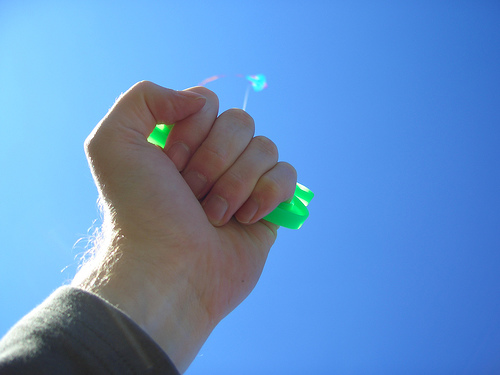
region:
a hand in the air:
[30, 59, 395, 269]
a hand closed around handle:
[64, 53, 371, 273]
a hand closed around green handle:
[49, 44, 381, 296]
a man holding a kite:
[42, 73, 401, 359]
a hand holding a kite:
[47, 6, 403, 310]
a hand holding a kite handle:
[22, 35, 384, 287]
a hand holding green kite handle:
[57, 32, 410, 296]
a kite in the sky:
[209, 31, 342, 165]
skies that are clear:
[321, 68, 494, 339]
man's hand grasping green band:
[82, 80, 296, 321]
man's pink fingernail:
[201, 193, 228, 225]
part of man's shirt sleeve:
[0, 285, 181, 373]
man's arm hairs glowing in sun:
[59, 192, 126, 296]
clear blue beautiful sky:
[2, 0, 497, 372]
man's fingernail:
[165, 141, 190, 172]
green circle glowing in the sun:
[250, 75, 265, 91]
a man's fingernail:
[182, 170, 205, 198]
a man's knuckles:
[135, 78, 296, 180]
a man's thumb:
[84, 80, 206, 232]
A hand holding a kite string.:
[70, 40, 335, 320]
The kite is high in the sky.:
[231, 60, 277, 95]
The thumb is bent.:
[80, 75, 195, 205]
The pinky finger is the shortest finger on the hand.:
[240, 155, 300, 230]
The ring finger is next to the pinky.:
[200, 130, 275, 230]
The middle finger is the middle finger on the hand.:
[180, 105, 240, 195]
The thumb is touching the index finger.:
[155, 80, 220, 165]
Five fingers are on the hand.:
[80, 35, 315, 280]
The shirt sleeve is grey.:
[0, 280, 196, 374]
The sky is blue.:
[360, 5, 498, 336]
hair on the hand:
[52, 227, 123, 287]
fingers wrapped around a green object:
[107, 75, 303, 241]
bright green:
[112, 110, 344, 235]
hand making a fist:
[66, 60, 341, 315]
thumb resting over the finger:
[120, 70, 220, 146]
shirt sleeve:
[2, 280, 177, 370]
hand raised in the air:
[4, 67, 342, 374]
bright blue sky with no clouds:
[3, 3, 492, 373]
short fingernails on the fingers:
[168, 146, 274, 234]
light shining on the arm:
[73, 209, 128, 276]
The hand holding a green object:
[87, 73, 314, 302]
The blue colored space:
[0, 0, 495, 374]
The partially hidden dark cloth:
[0, 280, 185, 370]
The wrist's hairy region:
[60, 177, 125, 322]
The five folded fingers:
[86, 80, 296, 225]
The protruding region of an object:
[240, 66, 266, 114]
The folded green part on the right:
[263, 181, 313, 227]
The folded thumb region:
[83, 80, 201, 150]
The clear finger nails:
[170, 86, 296, 226]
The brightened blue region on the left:
[2, 12, 142, 361]